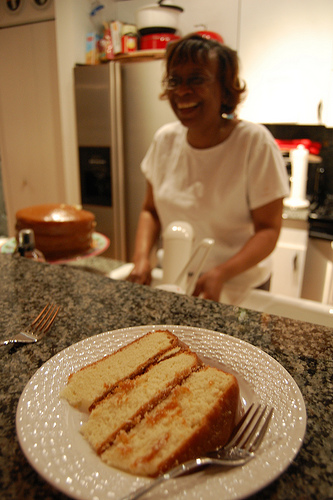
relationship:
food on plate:
[60, 327, 249, 474] [15, 321, 314, 494]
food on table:
[60, 327, 249, 474] [0, 247, 332, 498]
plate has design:
[15, 321, 314, 494] [17, 327, 309, 500]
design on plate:
[17, 327, 309, 500] [15, 321, 314, 494]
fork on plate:
[132, 399, 275, 496] [15, 321, 314, 494]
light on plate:
[23, 368, 307, 499] [15, 321, 314, 494]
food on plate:
[105, 363, 249, 474] [15, 321, 314, 494]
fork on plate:
[132, 399, 275, 496] [15, 321, 314, 498]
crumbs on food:
[110, 369, 193, 455] [105, 363, 249, 474]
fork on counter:
[1, 299, 61, 346] [3, 245, 332, 491]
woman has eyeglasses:
[120, 22, 295, 302] [160, 67, 225, 94]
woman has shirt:
[120, 22, 295, 302] [139, 108, 292, 285]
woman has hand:
[120, 22, 295, 302] [192, 271, 225, 301]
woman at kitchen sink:
[120, 22, 295, 302] [94, 216, 332, 326]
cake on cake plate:
[13, 201, 97, 263] [63, 230, 112, 264]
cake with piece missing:
[13, 201, 97, 263] [66, 206, 97, 259]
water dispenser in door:
[83, 147, 109, 205] [73, 60, 116, 259]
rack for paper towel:
[282, 141, 311, 211] [288, 151, 308, 203]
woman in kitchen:
[120, 22, 295, 302] [2, 3, 332, 495]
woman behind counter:
[120, 22, 295, 302] [3, 245, 332, 491]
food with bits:
[105, 363, 249, 474] [111, 376, 210, 443]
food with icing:
[105, 363, 249, 474] [86, 323, 200, 449]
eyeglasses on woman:
[160, 67, 225, 94] [120, 22, 295, 302]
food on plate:
[105, 363, 249, 474] [15, 321, 314, 498]